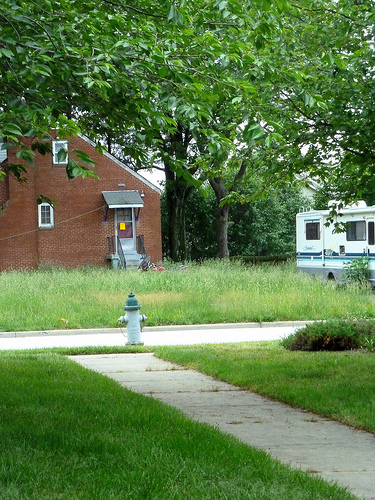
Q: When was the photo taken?
A: Daytime.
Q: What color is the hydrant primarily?
A: White.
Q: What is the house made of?
A: Brick.